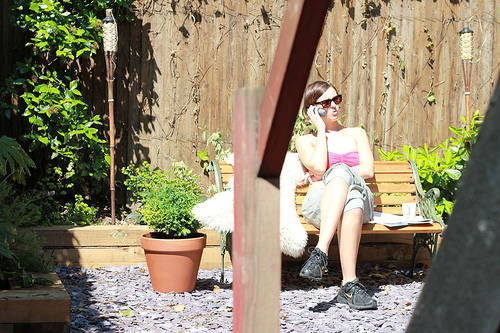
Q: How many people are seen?
A: One.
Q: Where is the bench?
A: On gravel.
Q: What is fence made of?
A: Wood.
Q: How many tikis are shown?
A: Two.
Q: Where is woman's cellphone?
A: In hand.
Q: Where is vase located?
A: On gravel.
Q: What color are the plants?
A: Green.